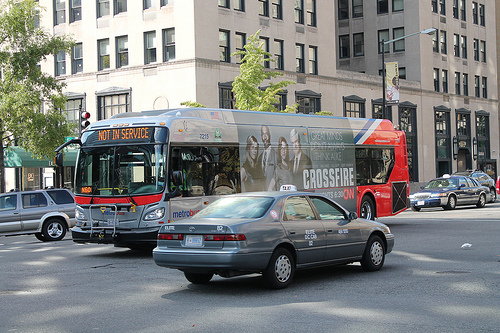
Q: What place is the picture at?
A: It is at the street.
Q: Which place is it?
A: It is a street.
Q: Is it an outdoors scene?
A: Yes, it is outdoors.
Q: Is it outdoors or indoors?
A: It is outdoors.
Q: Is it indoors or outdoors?
A: It is outdoors.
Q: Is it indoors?
A: No, it is outdoors.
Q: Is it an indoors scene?
A: No, it is outdoors.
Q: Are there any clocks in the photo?
A: No, there are no clocks.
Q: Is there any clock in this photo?
A: No, there are no clocks.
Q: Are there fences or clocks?
A: No, there are no clocks or fences.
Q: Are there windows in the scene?
A: Yes, there is a window.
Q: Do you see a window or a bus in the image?
A: Yes, there is a window.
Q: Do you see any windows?
A: Yes, there is a window.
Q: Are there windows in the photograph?
A: Yes, there is a window.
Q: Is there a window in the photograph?
A: Yes, there is a window.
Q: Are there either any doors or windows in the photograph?
A: Yes, there is a window.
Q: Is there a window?
A: Yes, there is a window.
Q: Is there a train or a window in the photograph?
A: Yes, there is a window.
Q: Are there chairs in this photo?
A: No, there are no chairs.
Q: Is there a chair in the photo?
A: No, there are no chairs.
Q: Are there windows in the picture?
A: Yes, there is a window.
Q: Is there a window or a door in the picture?
A: Yes, there is a window.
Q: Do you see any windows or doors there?
A: Yes, there is a window.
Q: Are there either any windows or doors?
A: Yes, there is a window.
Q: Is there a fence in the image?
A: No, there are no fences.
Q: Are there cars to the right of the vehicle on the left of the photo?
A: Yes, there is a car to the right of the vehicle.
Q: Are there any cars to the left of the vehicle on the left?
A: No, the car is to the right of the vehicle.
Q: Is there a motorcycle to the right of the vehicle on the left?
A: No, there is a car to the right of the vehicle.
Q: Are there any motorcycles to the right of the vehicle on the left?
A: No, there is a car to the right of the vehicle.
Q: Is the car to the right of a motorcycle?
A: No, the car is to the right of the vehicle.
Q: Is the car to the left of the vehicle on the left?
A: No, the car is to the right of the vehicle.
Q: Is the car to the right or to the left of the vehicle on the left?
A: The car is to the right of the vehicle.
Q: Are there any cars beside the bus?
A: Yes, there is a car beside the bus.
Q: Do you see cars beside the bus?
A: Yes, there is a car beside the bus.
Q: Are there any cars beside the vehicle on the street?
A: Yes, there is a car beside the bus.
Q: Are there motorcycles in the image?
A: No, there are no motorcycles.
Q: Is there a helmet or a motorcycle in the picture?
A: No, there are no motorcycles or helmets.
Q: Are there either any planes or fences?
A: No, there are no fences or planes.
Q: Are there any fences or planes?
A: No, there are no fences or planes.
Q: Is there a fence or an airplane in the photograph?
A: No, there are no fences or airplanes.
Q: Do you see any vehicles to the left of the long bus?
A: Yes, there is a vehicle to the left of the bus.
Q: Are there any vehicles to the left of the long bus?
A: Yes, there is a vehicle to the left of the bus.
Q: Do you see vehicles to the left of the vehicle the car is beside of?
A: Yes, there is a vehicle to the left of the bus.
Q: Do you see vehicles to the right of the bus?
A: No, the vehicle is to the left of the bus.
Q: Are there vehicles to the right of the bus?
A: No, the vehicle is to the left of the bus.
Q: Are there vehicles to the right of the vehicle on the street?
A: No, the vehicle is to the left of the bus.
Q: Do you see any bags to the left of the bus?
A: No, there is a vehicle to the left of the bus.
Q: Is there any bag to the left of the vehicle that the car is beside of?
A: No, there is a vehicle to the left of the bus.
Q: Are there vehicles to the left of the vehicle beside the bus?
A: Yes, there is a vehicle to the left of the car.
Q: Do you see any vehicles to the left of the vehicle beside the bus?
A: Yes, there is a vehicle to the left of the car.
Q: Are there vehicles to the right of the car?
A: No, the vehicle is to the left of the car.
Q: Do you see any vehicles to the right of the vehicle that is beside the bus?
A: No, the vehicle is to the left of the car.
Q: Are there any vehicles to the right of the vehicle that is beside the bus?
A: No, the vehicle is to the left of the car.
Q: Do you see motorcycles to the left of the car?
A: No, there is a vehicle to the left of the car.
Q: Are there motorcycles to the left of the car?
A: No, there is a vehicle to the left of the car.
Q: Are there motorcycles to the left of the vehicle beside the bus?
A: No, there is a vehicle to the left of the car.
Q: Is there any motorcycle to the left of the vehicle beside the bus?
A: No, there is a vehicle to the left of the car.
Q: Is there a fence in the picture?
A: No, there are no fences.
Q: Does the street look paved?
A: Yes, the street is paved.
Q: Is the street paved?
A: Yes, the street is paved.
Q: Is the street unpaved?
A: No, the street is paved.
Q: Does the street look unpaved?
A: No, the street is paved.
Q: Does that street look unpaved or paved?
A: The street is paved.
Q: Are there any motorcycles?
A: No, there are no motorcycles.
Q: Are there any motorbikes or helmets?
A: No, there are no motorbikes or helmets.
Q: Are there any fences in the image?
A: No, there are no fences.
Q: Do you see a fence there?
A: No, there are no fences.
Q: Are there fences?
A: No, there are no fences.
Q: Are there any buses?
A: Yes, there is a bus.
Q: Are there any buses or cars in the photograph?
A: Yes, there is a bus.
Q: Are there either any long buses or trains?
A: Yes, there is a long bus.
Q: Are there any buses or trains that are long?
A: Yes, the bus is long.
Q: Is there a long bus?
A: Yes, there is a long bus.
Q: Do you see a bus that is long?
A: Yes, there is a bus that is long.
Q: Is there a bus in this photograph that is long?
A: Yes, there is a bus that is long.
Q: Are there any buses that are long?
A: Yes, there is a bus that is long.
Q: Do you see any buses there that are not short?
A: Yes, there is a long bus.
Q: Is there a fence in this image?
A: No, there are no fences.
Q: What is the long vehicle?
A: The vehicle is a bus.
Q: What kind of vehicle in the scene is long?
A: The vehicle is a bus.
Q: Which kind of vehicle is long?
A: The vehicle is a bus.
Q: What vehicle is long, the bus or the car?
A: The bus is long.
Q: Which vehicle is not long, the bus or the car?
A: The car is not long.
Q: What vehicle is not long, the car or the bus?
A: The car is not long.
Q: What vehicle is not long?
A: The vehicle is a car.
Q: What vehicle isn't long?
A: The vehicle is a car.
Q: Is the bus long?
A: Yes, the bus is long.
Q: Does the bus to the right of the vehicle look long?
A: Yes, the bus is long.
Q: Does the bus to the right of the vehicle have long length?
A: Yes, the bus is long.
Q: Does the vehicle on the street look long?
A: Yes, the bus is long.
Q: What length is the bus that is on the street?
A: The bus is long.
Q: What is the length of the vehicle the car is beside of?
A: The bus is long.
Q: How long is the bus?
A: The bus is long.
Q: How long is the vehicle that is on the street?
A: The bus is long.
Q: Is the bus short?
A: No, the bus is long.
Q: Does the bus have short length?
A: No, the bus is long.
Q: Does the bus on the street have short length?
A: No, the bus is long.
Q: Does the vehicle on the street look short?
A: No, the bus is long.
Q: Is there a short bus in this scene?
A: No, there is a bus but it is long.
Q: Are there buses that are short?
A: No, there is a bus but it is long.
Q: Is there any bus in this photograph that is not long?
A: No, there is a bus but it is long.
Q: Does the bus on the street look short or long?
A: The bus is long.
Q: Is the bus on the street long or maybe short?
A: The bus is long.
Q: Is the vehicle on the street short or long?
A: The bus is long.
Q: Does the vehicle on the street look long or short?
A: The bus is long.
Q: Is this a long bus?
A: Yes, this is a long bus.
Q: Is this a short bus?
A: No, this is a long bus.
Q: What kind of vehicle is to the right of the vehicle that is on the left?
A: The vehicle is a bus.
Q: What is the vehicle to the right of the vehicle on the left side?
A: The vehicle is a bus.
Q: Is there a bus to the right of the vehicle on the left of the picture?
A: Yes, there is a bus to the right of the vehicle.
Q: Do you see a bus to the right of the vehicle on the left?
A: Yes, there is a bus to the right of the vehicle.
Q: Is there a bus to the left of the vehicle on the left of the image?
A: No, the bus is to the right of the vehicle.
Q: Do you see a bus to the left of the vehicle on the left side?
A: No, the bus is to the right of the vehicle.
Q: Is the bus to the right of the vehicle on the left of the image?
A: Yes, the bus is to the right of the vehicle.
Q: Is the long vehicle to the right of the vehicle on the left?
A: Yes, the bus is to the right of the vehicle.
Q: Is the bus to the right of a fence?
A: No, the bus is to the right of the vehicle.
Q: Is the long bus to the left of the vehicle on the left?
A: No, the bus is to the right of the vehicle.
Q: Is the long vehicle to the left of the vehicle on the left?
A: No, the bus is to the right of the vehicle.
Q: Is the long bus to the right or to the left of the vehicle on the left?
A: The bus is to the right of the vehicle.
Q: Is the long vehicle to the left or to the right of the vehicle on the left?
A: The bus is to the right of the vehicle.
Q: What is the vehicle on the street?
A: The vehicle is a bus.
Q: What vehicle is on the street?
A: The vehicle is a bus.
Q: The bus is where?
A: The bus is on the street.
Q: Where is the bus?
A: The bus is on the street.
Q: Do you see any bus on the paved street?
A: Yes, there is a bus on the street.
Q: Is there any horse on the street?
A: No, there is a bus on the street.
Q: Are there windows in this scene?
A: Yes, there is a window.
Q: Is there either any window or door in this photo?
A: Yes, there is a window.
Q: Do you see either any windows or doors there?
A: Yes, there is a window.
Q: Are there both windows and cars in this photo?
A: Yes, there are both a window and a car.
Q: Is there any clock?
A: No, there are no clocks.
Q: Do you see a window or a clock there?
A: Yes, there is a window.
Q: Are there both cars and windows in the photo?
A: Yes, there are both a window and a car.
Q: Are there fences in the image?
A: No, there are no fences.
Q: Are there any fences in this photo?
A: No, there are no fences.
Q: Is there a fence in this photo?
A: No, there are no fences.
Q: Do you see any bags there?
A: No, there are no bags.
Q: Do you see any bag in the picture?
A: No, there are no bags.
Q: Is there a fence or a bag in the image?
A: No, there are no bags or fences.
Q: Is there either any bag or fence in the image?
A: No, there are no bags or fences.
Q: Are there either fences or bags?
A: No, there are no bags or fences.